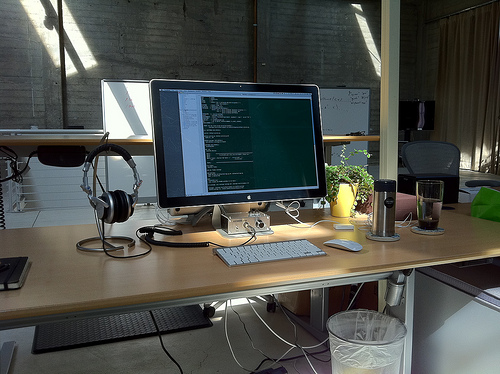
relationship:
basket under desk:
[323, 307, 406, 374] [1, 182, 498, 326]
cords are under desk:
[208, 281, 370, 373] [1, 182, 498, 326]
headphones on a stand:
[79, 143, 143, 225] [77, 132, 135, 195]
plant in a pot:
[324, 149, 373, 204] [326, 178, 359, 219]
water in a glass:
[415, 197, 443, 230] [414, 178, 444, 234]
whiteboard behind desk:
[99, 77, 163, 140] [1, 129, 384, 151]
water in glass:
[415, 197, 443, 230] [414, 178, 444, 234]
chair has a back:
[398, 139, 460, 204] [401, 139, 461, 174]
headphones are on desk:
[80, 142, 142, 223] [1, 182, 498, 326]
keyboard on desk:
[210, 238, 326, 266] [1, 182, 498, 326]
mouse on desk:
[323, 237, 364, 253] [1, 182, 498, 326]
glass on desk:
[414, 178, 444, 234] [1, 182, 498, 326]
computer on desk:
[146, 76, 329, 236] [1, 182, 498, 326]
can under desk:
[323, 307, 406, 374] [1, 182, 498, 326]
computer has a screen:
[146, 76, 329, 236] [157, 86, 317, 190]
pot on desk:
[326, 178, 359, 219] [1, 182, 498, 326]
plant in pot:
[324, 149, 373, 204] [326, 178, 359, 219]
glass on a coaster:
[414, 178, 444, 234] [365, 231, 401, 243]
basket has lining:
[323, 307, 406, 374] [337, 314, 398, 374]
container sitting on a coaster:
[369, 178, 397, 237] [365, 231, 401, 243]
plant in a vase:
[324, 149, 373, 204] [326, 178, 359, 219]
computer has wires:
[146, 76, 329, 236] [137, 205, 336, 248]